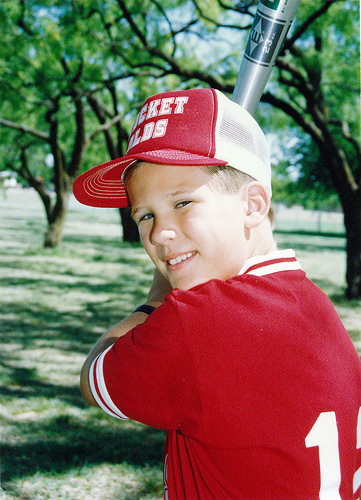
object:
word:
[128, 96, 189, 133]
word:
[125, 118, 168, 157]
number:
[304, 410, 342, 499]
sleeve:
[87, 287, 201, 443]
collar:
[237, 248, 302, 278]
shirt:
[87, 246, 361, 499]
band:
[132, 304, 155, 317]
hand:
[146, 266, 173, 303]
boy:
[72, 87, 360, 500]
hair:
[203, 164, 276, 228]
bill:
[72, 147, 227, 208]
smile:
[161, 250, 198, 272]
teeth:
[169, 251, 199, 266]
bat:
[233, 0, 300, 116]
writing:
[122, 95, 189, 156]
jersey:
[88, 250, 361, 499]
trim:
[88, 342, 132, 422]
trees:
[0, 2, 361, 298]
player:
[73, 90, 361, 500]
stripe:
[87, 343, 131, 423]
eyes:
[138, 196, 198, 223]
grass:
[0, 378, 86, 499]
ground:
[0, 240, 166, 500]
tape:
[132, 304, 156, 316]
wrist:
[130, 290, 164, 317]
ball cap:
[72, 86, 272, 209]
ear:
[244, 180, 270, 229]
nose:
[151, 216, 180, 245]